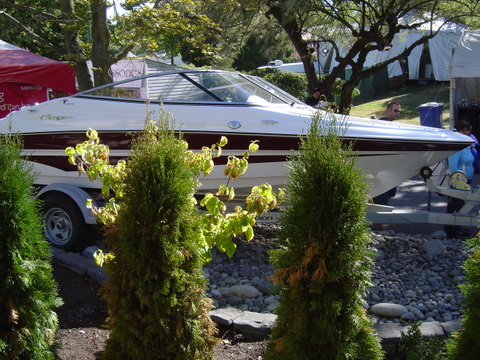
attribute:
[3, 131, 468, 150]
stripe — big, purple, white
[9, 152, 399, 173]
stripe — white, purple, big